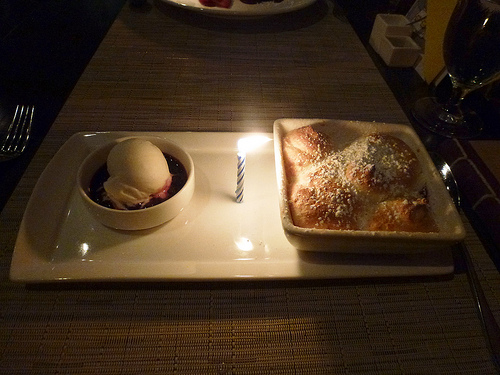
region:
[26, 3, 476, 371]
bamboo table runner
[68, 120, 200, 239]
vanilla ice cream in a bowl with sauce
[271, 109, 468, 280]
pastry in a rectangular dish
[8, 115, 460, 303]
white ceramic serving tray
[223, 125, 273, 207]
lit blue and white candle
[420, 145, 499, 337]
silver metal spoon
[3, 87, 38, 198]
silver metal fork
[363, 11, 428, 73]
square white ceramic bowls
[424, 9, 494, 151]
glass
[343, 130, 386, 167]
sweet white powdered sugar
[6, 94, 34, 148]
fork on the table.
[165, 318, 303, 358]
placemat on the table.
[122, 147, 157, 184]
ice cream in dish.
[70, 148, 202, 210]
dish on the tray.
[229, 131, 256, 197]
candle on the tray.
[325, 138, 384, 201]
dessert in serving dish.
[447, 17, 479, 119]
glass on the table.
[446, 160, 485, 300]
silverware on the right.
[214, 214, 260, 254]
reflection on the tray.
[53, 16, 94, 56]
wooden table in dining room.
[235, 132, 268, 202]
blue and white birthday candle is lit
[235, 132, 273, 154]
glowing flame on birthday candle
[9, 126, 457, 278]
ceramic white rectangular tray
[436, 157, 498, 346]
metal spoon to the right of tray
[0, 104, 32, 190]
metal fork to the left of tray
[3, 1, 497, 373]
brown woven runner on table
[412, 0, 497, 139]
clear glass goblet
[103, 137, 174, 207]
scoop of vanilla ice cream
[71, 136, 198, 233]
round white bowl on tray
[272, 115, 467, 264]
pastry in a square white dish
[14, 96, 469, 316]
Food sitting in containers on tray.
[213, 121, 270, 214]
Burning candle sitting on tray on table.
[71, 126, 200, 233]
Ice cream sitting on purple sauce in bowl.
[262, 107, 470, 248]
Food in square container covered with powdered sugar.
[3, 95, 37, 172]
Tines of a fork sitting by tray.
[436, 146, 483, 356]
Spoon sitting by tray next to powdered sugar covered food.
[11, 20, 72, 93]
Edge of brown table under textured mat runner..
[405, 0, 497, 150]
Glass of brown liquid sitting on table.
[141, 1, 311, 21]
Edge of plate sitting on table.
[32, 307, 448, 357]
Brown textured mat runner under tray.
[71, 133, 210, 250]
Icecream in a bowel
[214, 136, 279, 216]
Candle on a plate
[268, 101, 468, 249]
Bowel of food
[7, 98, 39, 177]
Fork on a table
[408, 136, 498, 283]
Spoon on a table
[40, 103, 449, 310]
White tray on a table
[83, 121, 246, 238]
Berries in a bowel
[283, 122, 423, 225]
Dessert in a bowel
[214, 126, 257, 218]
Blue birthday candle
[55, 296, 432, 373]
Bamboo table runner on a table